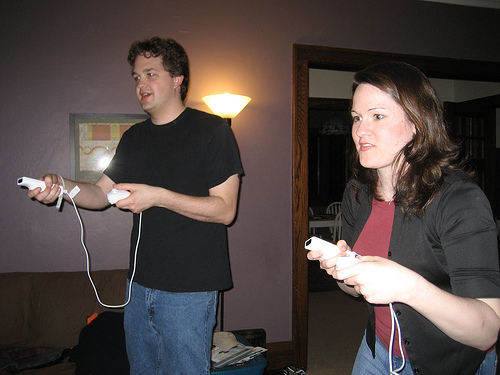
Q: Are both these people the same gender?
A: No, they are both male and female.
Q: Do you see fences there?
A: No, there are no fences.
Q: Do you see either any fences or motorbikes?
A: No, there are no fences or motorbikes.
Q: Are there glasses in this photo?
A: No, there are no glasses.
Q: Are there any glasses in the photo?
A: No, there are no glasses.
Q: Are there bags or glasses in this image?
A: No, there are no glasses or bags.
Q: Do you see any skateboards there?
A: No, there are no skateboards.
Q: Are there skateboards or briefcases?
A: No, there are no skateboards or briefcases.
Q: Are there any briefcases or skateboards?
A: No, there are no skateboards or briefcases.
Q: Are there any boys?
A: No, there are no boys.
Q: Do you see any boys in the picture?
A: No, there are no boys.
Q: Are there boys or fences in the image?
A: No, there are no boys or fences.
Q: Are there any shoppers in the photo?
A: No, there are no shoppers.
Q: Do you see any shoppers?
A: No, there are no shoppers.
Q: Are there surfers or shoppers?
A: No, there are no shoppers or surfers.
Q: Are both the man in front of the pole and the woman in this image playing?
A: Yes, both the man and the woman are playing.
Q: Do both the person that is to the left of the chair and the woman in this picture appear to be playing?
A: Yes, both the man and the woman are playing.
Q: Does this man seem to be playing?
A: Yes, the man is playing.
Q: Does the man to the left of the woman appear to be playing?
A: Yes, the man is playing.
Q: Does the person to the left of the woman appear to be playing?
A: Yes, the man is playing.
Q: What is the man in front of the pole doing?
A: The man is playing.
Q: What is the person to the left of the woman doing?
A: The man is playing.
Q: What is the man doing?
A: The man is playing.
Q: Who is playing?
A: The man is playing.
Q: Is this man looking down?
A: No, the man is playing.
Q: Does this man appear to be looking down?
A: No, the man is playing.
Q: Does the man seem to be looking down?
A: No, the man is playing.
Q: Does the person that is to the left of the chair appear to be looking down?
A: No, the man is playing.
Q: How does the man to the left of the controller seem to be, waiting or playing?
A: The man is playing.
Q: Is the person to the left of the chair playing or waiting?
A: The man is playing.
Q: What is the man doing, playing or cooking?
A: The man is playing.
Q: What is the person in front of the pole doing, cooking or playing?
A: The man is playing.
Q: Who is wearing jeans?
A: The man is wearing jeans.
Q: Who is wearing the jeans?
A: The man is wearing jeans.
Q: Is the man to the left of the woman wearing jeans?
A: Yes, the man is wearing jeans.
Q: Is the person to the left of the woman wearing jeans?
A: Yes, the man is wearing jeans.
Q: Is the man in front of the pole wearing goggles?
A: No, the man is wearing jeans.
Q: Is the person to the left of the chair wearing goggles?
A: No, the man is wearing jeans.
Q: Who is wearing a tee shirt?
A: The man is wearing a tee shirt.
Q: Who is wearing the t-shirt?
A: The man is wearing a tee shirt.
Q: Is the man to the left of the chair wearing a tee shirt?
A: Yes, the man is wearing a tee shirt.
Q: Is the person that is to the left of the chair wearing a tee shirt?
A: Yes, the man is wearing a tee shirt.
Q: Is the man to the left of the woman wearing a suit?
A: No, the man is wearing a tee shirt.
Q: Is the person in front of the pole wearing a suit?
A: No, the man is wearing a tee shirt.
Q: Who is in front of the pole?
A: The man is in front of the pole.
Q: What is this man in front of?
A: The man is in front of the pole.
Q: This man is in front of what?
A: The man is in front of the pole.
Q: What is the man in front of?
A: The man is in front of the pole.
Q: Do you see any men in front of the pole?
A: Yes, there is a man in front of the pole.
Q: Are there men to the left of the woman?
A: Yes, there is a man to the left of the woman.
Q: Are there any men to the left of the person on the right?
A: Yes, there is a man to the left of the woman.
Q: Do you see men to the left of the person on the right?
A: Yes, there is a man to the left of the woman.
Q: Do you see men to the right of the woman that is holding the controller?
A: No, the man is to the left of the woman.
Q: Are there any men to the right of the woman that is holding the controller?
A: No, the man is to the left of the woman.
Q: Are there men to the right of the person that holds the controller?
A: No, the man is to the left of the woman.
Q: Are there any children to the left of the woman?
A: No, there is a man to the left of the woman.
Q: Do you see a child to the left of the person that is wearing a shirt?
A: No, there is a man to the left of the woman.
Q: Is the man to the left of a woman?
A: Yes, the man is to the left of a woman.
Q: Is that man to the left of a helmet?
A: No, the man is to the left of a woman.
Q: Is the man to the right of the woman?
A: No, the man is to the left of the woman.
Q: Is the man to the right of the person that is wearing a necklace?
A: No, the man is to the left of the woman.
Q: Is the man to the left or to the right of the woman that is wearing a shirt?
A: The man is to the left of the woman.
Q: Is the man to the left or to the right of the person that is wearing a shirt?
A: The man is to the left of the woman.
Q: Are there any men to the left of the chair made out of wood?
A: Yes, there is a man to the left of the chair.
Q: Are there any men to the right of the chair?
A: No, the man is to the left of the chair.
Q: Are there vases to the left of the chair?
A: No, there is a man to the left of the chair.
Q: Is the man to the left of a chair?
A: Yes, the man is to the left of a chair.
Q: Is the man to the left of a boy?
A: No, the man is to the left of a chair.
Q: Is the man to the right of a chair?
A: No, the man is to the left of a chair.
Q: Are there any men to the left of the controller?
A: Yes, there is a man to the left of the controller.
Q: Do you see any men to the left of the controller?
A: Yes, there is a man to the left of the controller.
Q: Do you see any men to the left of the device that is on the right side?
A: Yes, there is a man to the left of the controller.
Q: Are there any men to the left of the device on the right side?
A: Yes, there is a man to the left of the controller.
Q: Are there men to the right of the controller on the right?
A: No, the man is to the left of the controller.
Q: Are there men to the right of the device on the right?
A: No, the man is to the left of the controller.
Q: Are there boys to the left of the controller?
A: No, there is a man to the left of the controller.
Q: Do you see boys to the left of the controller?
A: No, there is a man to the left of the controller.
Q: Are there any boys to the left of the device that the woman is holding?
A: No, there is a man to the left of the controller.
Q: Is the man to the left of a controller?
A: Yes, the man is to the left of a controller.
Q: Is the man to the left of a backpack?
A: No, the man is to the left of a controller.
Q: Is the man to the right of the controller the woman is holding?
A: No, the man is to the left of the controller.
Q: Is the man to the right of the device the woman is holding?
A: No, the man is to the left of the controller.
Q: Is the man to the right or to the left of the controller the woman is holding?
A: The man is to the left of the controller.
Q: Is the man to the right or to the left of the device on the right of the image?
A: The man is to the left of the controller.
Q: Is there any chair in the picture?
A: Yes, there is a chair.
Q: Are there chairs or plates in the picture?
A: Yes, there is a chair.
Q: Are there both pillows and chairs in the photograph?
A: No, there is a chair but no pillows.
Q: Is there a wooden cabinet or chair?
A: Yes, there is a wood chair.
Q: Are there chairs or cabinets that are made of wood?
A: Yes, the chair is made of wood.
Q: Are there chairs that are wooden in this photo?
A: Yes, there is a wood chair.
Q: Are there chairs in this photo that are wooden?
A: Yes, there is a chair that is wooden.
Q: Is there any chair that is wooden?
A: Yes, there is a chair that is wooden.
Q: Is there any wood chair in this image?
A: Yes, there is a chair that is made of wood.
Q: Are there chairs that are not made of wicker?
A: Yes, there is a chair that is made of wood.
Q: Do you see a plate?
A: No, there are no plates.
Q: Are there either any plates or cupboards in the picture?
A: No, there are no plates or cupboards.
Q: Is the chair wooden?
A: Yes, the chair is wooden.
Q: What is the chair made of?
A: The chair is made of wood.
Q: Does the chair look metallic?
A: No, the chair is wooden.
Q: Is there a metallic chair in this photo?
A: No, there is a chair but it is wooden.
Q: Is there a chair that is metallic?
A: No, there is a chair but it is wooden.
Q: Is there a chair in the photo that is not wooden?
A: No, there is a chair but it is wooden.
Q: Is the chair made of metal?
A: No, the chair is made of wood.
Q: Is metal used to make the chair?
A: No, the chair is made of wood.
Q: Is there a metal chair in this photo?
A: No, there is a chair but it is made of wood.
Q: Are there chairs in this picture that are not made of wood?
A: No, there is a chair but it is made of wood.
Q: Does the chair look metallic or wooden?
A: The chair is wooden.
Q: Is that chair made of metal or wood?
A: The chair is made of wood.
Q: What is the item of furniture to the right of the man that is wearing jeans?
A: The piece of furniture is a chair.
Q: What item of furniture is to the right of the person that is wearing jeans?
A: The piece of furniture is a chair.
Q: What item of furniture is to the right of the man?
A: The piece of furniture is a chair.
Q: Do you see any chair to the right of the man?
A: Yes, there is a chair to the right of the man.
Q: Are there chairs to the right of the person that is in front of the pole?
A: Yes, there is a chair to the right of the man.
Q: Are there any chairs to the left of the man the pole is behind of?
A: No, the chair is to the right of the man.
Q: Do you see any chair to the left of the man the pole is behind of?
A: No, the chair is to the right of the man.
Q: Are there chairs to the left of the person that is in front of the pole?
A: No, the chair is to the right of the man.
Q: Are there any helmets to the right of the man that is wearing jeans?
A: No, there is a chair to the right of the man.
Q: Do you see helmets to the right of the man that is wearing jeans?
A: No, there is a chair to the right of the man.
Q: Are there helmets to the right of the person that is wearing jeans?
A: No, there is a chair to the right of the man.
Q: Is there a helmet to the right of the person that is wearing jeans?
A: No, there is a chair to the right of the man.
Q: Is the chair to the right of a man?
A: Yes, the chair is to the right of a man.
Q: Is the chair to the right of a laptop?
A: No, the chair is to the right of a man.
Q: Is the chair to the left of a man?
A: No, the chair is to the right of a man.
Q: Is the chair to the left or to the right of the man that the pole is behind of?
A: The chair is to the right of the man.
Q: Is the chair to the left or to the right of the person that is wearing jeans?
A: The chair is to the right of the man.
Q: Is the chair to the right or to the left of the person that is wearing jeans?
A: The chair is to the right of the man.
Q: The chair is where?
A: The chair is at the table.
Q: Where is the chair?
A: The chair is at the table.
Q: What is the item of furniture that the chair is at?
A: The piece of furniture is a table.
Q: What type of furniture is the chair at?
A: The chair is at the table.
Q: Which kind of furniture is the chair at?
A: The chair is at the table.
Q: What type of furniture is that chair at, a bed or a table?
A: The chair is at a table.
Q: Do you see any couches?
A: Yes, there is a couch.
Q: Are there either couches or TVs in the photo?
A: Yes, there is a couch.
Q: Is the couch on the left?
A: Yes, the couch is on the left of the image.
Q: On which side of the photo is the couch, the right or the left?
A: The couch is on the left of the image.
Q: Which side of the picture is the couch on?
A: The couch is on the left of the image.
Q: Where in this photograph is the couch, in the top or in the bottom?
A: The couch is in the bottom of the image.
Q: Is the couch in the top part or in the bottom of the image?
A: The couch is in the bottom of the image.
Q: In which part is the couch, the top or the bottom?
A: The couch is in the bottom of the image.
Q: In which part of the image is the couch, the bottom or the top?
A: The couch is in the bottom of the image.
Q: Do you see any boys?
A: No, there are no boys.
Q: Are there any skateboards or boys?
A: No, there are no boys or skateboards.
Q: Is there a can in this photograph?
A: No, there are no cans.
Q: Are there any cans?
A: No, there are no cans.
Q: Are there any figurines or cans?
A: No, there are no cans or figurines.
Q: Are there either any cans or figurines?
A: No, there are no cans or figurines.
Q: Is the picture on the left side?
A: Yes, the picture is on the left of the image.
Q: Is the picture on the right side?
A: No, the picture is on the left of the image.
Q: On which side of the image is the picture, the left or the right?
A: The picture is on the left of the image.